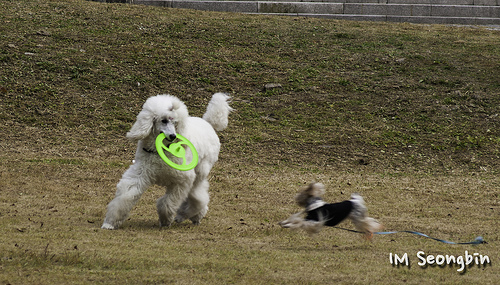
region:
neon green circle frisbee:
[151, 128, 198, 178]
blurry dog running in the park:
[286, 175, 369, 255]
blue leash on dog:
[339, 219, 487, 259]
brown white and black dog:
[281, 179, 375, 246]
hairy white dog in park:
[99, 75, 227, 235]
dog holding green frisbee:
[99, 62, 240, 230]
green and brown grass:
[3, 2, 488, 282]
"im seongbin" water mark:
[388, 242, 498, 272]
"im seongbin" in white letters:
[387, 247, 491, 274]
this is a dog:
[101, 75, 201, 237]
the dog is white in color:
[198, 118, 211, 158]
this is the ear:
[120, 109, 159, 135]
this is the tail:
[207, 90, 239, 121]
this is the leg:
[91, 169, 143, 247]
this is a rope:
[349, 220, 439, 245]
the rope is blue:
[393, 224, 442, 247]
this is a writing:
[378, 234, 478, 284]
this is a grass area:
[283, 57, 369, 110]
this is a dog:
[99, 88, 231, 239]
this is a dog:
[279, 181, 377, 238]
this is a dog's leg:
[104, 159, 158, 237]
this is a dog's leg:
[157, 168, 199, 228]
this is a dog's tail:
[207, 85, 237, 146]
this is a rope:
[309, 213, 485, 252]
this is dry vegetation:
[10, 233, 119, 282]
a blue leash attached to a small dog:
[312, 220, 487, 248]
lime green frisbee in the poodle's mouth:
[152, 131, 203, 176]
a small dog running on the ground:
[270, 178, 382, 240]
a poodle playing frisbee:
[97, 81, 243, 235]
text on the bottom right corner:
[390, 239, 499, 264]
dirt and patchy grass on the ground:
[1, 11, 496, 281]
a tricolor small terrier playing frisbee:
[272, 174, 387, 249]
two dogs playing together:
[96, 87, 487, 247]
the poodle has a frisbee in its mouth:
[103, 82, 239, 234]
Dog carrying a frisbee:
[150, 126, 200, 176]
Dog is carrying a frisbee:
[150, 128, 202, 173]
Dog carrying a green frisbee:
[147, 130, 205, 175]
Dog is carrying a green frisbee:
[151, 126, 206, 174]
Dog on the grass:
[100, 77, 234, 232]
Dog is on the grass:
[92, 72, 246, 228]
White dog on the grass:
[100, 87, 235, 230]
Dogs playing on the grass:
[100, 74, 386, 245]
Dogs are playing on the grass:
[87, 86, 383, 243]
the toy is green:
[154, 130, 198, 172]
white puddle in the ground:
[103, 86, 231, 233]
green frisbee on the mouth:
[155, 128, 200, 170]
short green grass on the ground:
[4, 2, 493, 282]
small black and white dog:
[285, 182, 377, 240]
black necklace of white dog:
[139, 144, 163, 156]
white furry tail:
[202, 85, 230, 131]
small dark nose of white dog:
[164, 130, 177, 143]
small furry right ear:
[125, 110, 151, 140]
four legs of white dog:
[100, 165, 212, 228]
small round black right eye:
[159, 111, 171, 128]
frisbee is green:
[158, 127, 193, 174]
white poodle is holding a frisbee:
[99, 88, 226, 218]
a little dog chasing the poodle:
[284, 180, 376, 242]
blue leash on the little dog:
[311, 213, 486, 246]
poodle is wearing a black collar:
[87, 91, 234, 226]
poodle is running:
[90, 90, 230, 227]